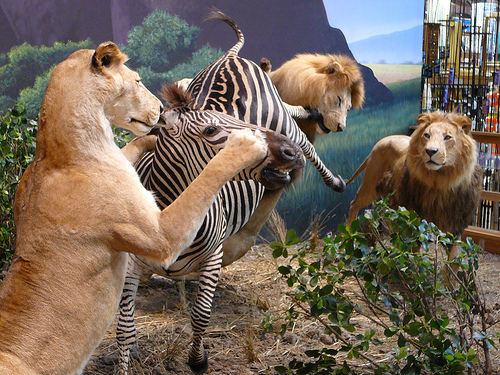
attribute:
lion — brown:
[265, 51, 366, 146]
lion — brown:
[314, 116, 434, 197]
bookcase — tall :
[416, 60, 498, 232]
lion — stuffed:
[344, 111, 481, 233]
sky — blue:
[322, 0, 497, 62]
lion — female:
[209, 45, 366, 244]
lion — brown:
[349, 101, 482, 258]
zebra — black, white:
[113, 5, 350, 372]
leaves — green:
[283, 200, 495, 373]